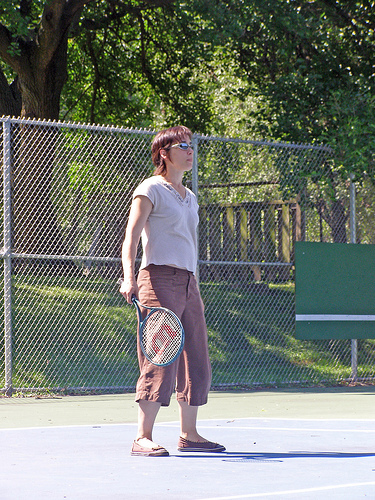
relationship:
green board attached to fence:
[293, 238, 373, 343] [195, 130, 354, 387]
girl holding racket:
[83, 104, 237, 469] [84, 286, 216, 378]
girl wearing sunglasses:
[117, 125, 226, 458] [168, 144, 206, 158]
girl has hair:
[117, 125, 226, 458] [148, 126, 192, 176]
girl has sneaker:
[117, 125, 226, 458] [128, 438, 171, 457]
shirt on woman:
[131, 175, 203, 275] [103, 130, 291, 434]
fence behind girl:
[0, 114, 373, 392] [117, 125, 226, 458]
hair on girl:
[148, 126, 190, 175] [117, 125, 226, 458]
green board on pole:
[293, 238, 373, 343] [0, 118, 16, 398]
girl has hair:
[117, 125, 226, 458] [145, 124, 190, 143]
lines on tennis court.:
[250, 426, 369, 432] [45, 82, 373, 449]